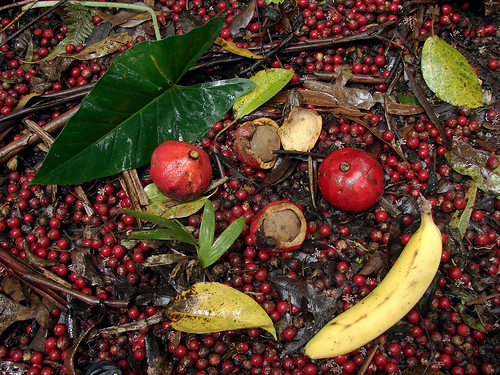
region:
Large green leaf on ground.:
[80, 63, 213, 109]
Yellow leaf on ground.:
[168, 276, 244, 346]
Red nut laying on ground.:
[153, 135, 215, 195]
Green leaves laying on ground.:
[141, 213, 253, 254]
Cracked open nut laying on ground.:
[241, 114, 301, 139]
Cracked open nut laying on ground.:
[236, 188, 347, 269]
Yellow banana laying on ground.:
[340, 230, 422, 325]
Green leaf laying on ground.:
[412, 42, 499, 112]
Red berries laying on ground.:
[43, 333, 59, 344]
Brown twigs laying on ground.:
[46, 25, 403, 66]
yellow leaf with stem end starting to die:
[159, 279, 280, 346]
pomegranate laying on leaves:
[145, 132, 220, 202]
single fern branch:
[13, 0, 98, 65]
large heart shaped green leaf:
[24, 9, 261, 193]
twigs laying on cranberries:
[240, 5, 416, 88]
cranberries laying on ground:
[4, 195, 121, 280]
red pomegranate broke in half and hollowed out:
[231, 97, 325, 176]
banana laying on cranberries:
[298, 185, 460, 362]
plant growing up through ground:
[107, 193, 242, 280]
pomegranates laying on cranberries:
[144, 100, 395, 253]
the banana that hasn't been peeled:
[300, 194, 441, 360]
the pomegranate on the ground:
[317, 147, 384, 209]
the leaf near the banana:
[167, 281, 276, 342]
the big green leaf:
[28, 16, 254, 192]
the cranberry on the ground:
[353, 272, 364, 284]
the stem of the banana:
[415, 192, 433, 222]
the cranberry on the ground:
[375, 210, 387, 221]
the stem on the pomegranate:
[339, 160, 351, 172]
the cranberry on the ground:
[438, 354, 451, 368]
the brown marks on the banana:
[299, 192, 441, 359]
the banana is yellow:
[331, 211, 466, 366]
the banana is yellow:
[249, 193, 434, 370]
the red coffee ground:
[243, 255, 281, 292]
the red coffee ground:
[258, 274, 289, 325]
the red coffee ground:
[386, 170, 443, 223]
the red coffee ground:
[43, 196, 75, 260]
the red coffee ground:
[230, 321, 260, 372]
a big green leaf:
[48, 58, 238, 205]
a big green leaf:
[20, 38, 289, 267]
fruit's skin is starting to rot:
[235, 111, 345, 192]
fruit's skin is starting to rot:
[265, 198, 324, 273]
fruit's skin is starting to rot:
[226, 200, 336, 257]